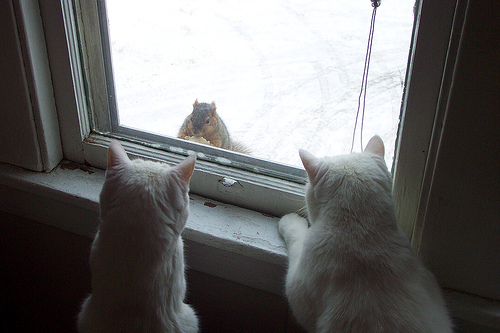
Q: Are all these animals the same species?
A: Yes, all the animals are cats.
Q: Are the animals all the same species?
A: Yes, all the animals are cats.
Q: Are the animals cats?
A: Yes, all the animals are cats.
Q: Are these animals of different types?
A: No, all the animals are cats.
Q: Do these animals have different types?
A: No, all the animals are cats.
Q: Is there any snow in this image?
A: Yes, there is snow.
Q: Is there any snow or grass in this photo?
A: Yes, there is snow.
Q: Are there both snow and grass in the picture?
A: No, there is snow but no grass.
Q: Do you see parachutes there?
A: No, there are no parachutes.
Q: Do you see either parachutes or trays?
A: No, there are no parachutes or trays.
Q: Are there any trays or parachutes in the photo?
A: No, there are no parachutes or trays.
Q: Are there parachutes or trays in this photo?
A: No, there are no parachutes or trays.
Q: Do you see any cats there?
A: Yes, there is a cat.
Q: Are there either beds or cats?
A: Yes, there is a cat.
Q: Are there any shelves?
A: No, there are no shelves.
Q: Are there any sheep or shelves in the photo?
A: No, there are no shelves or sheep.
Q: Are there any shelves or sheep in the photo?
A: No, there are no shelves or sheep.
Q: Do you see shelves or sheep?
A: No, there are no shelves or sheep.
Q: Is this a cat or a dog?
A: This is a cat.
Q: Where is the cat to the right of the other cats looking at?
A: The cat is looking outside.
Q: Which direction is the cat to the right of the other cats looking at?
A: The cat is looking outside.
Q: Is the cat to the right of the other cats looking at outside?
A: Yes, the cat is looking outside.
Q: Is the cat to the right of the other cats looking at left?
A: No, the cat is looking outside.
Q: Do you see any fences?
A: No, there are no fences.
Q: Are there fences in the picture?
A: No, there are no fences.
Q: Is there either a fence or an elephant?
A: No, there are no fences or elephants.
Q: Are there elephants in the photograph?
A: No, there are no elephants.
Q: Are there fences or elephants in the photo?
A: No, there are no elephants or fences.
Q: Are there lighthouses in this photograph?
A: No, there are no lighthouses.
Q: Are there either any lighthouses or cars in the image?
A: No, there are no lighthouses or cars.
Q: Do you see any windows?
A: Yes, there is a window.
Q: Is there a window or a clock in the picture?
A: Yes, there is a window.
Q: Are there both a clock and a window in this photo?
A: No, there is a window but no clocks.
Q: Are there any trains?
A: No, there are no trains.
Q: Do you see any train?
A: No, there are no trains.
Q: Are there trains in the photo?
A: No, there are no trains.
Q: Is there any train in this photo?
A: No, there are no trains.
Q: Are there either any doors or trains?
A: No, there are no trains or doors.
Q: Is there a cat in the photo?
A: Yes, there are cats.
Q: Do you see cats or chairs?
A: Yes, there are cats.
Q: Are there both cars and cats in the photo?
A: No, there are cats but no cars.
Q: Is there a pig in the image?
A: No, there are no pigs.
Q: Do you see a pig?
A: No, there are no pigs.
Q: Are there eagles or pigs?
A: No, there are no pigs or eagles.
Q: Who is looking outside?
A: The cats are looking outside.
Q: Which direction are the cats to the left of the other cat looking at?
A: The cats are looking outside.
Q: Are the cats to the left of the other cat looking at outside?
A: Yes, the cats are looking outside.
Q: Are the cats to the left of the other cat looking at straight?
A: No, the cats are looking outside.